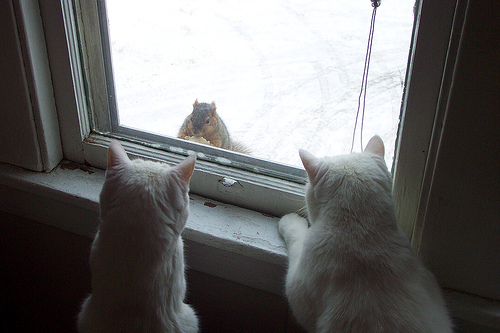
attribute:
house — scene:
[4, 1, 498, 330]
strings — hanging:
[343, 3, 382, 150]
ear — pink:
[296, 146, 333, 178]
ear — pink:
[365, 132, 385, 159]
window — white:
[38, 0, 463, 267]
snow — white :
[115, 7, 360, 107]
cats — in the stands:
[66, 135, 449, 332]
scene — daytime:
[2, 0, 497, 331]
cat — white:
[279, 134, 454, 331]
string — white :
[349, 50, 379, 153]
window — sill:
[49, 1, 434, 232]